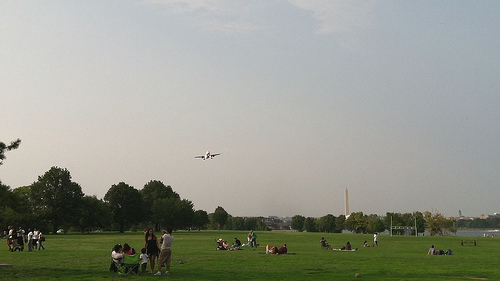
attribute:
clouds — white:
[304, 3, 381, 39]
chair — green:
[119, 250, 142, 277]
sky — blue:
[201, 32, 375, 124]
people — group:
[9, 223, 54, 263]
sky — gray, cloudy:
[224, 63, 347, 120]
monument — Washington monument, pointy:
[344, 188, 352, 220]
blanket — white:
[329, 247, 356, 252]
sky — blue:
[3, 2, 495, 214]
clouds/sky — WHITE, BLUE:
[163, 0, 385, 79]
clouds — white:
[291, 0, 399, 49]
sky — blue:
[207, 37, 407, 119]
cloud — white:
[163, 1, 372, 41]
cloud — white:
[165, 2, 362, 37]